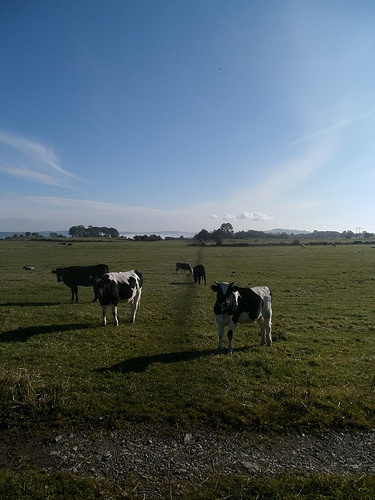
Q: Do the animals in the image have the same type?
A: Yes, all the animals are cows.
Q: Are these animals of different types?
A: No, all the animals are cows.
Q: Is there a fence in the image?
A: No, there are no fences.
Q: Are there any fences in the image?
A: No, there are no fences.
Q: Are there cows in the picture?
A: Yes, there is a cow.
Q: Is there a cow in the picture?
A: Yes, there is a cow.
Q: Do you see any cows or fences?
A: Yes, there is a cow.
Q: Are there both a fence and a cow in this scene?
A: No, there is a cow but no fences.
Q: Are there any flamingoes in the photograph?
A: No, there are no flamingoes.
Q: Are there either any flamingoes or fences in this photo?
A: No, there are no flamingoes or fences.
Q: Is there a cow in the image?
A: Yes, there is a cow.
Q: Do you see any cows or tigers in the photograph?
A: Yes, there is a cow.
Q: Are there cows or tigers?
A: Yes, there is a cow.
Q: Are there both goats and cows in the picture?
A: No, there is a cow but no goats.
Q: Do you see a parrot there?
A: No, there are no parrots.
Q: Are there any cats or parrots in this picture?
A: No, there are no parrots or cats.